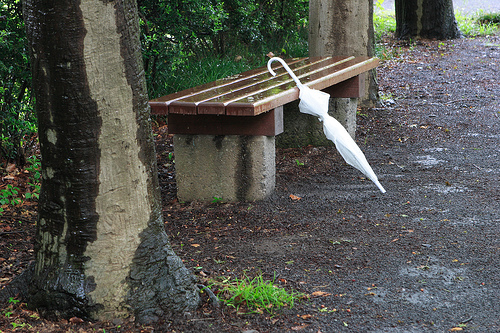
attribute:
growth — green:
[207, 195, 221, 201]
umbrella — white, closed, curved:
[265, 55, 387, 196]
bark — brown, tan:
[18, 0, 234, 325]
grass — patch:
[215, 273, 297, 308]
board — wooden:
[147, 51, 304, 106]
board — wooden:
[176, 47, 328, 107]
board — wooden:
[197, 48, 352, 114]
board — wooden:
[222, 56, 379, 117]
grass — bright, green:
[205, 274, 293, 315]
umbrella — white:
[267, 47, 399, 220]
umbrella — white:
[300, 70, 431, 184]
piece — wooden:
[165, 104, 285, 137]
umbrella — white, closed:
[281, 80, 401, 187]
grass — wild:
[180, 45, 236, 92]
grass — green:
[213, 263, 297, 313]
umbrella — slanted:
[262, 47, 388, 193]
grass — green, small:
[224, 280, 294, 312]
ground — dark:
[168, 28, 496, 330]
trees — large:
[48, 18, 383, 223]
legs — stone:
[170, 132, 275, 203]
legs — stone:
[275, 97, 356, 145]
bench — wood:
[177, 19, 425, 250]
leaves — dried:
[289, 311, 311, 331]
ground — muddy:
[0, 16, 499, 330]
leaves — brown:
[367, 50, 452, 116]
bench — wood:
[163, 50, 370, 202]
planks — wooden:
[152, 97, 254, 114]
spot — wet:
[368, 255, 490, 313]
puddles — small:
[390, 139, 480, 318]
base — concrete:
[160, 130, 280, 205]